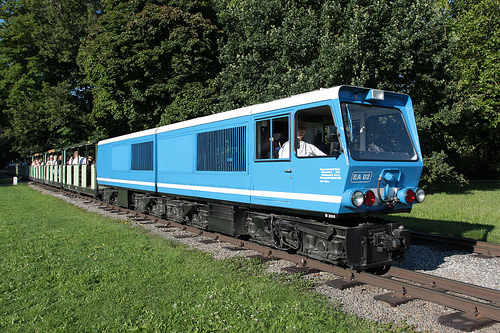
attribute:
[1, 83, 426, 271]
train — blue, running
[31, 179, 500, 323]
tracks — brown, black, metal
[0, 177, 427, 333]
grass — green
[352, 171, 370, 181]
numbers — white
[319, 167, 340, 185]
lettering — white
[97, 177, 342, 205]
stripe — white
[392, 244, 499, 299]
gravel — gray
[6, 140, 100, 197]
cars — green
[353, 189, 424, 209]
headlights — colored